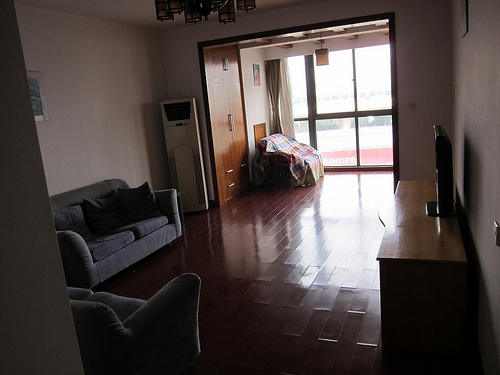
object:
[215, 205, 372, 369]
floor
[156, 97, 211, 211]
appliance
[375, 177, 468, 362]
cabinet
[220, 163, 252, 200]
drawers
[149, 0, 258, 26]
light fixture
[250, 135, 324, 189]
chair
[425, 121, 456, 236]
tv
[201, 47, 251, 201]
closet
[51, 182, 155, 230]
pillows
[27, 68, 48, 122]
artwork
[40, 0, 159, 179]
wall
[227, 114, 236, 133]
handles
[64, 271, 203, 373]
loveseat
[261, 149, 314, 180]
blanket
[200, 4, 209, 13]
lamp shade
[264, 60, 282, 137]
curtains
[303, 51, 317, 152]
division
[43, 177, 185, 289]
couch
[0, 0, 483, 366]
office